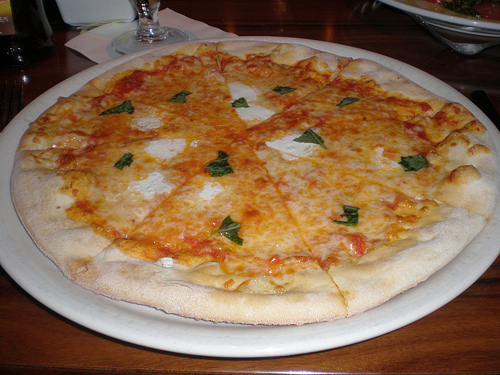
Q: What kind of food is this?
A: Pizza.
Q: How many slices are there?
A: Eight.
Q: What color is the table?
A: Brown.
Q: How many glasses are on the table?
A: One.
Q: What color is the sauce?
A: Red.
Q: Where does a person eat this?
A: At the table.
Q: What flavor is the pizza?
A: Cheese.